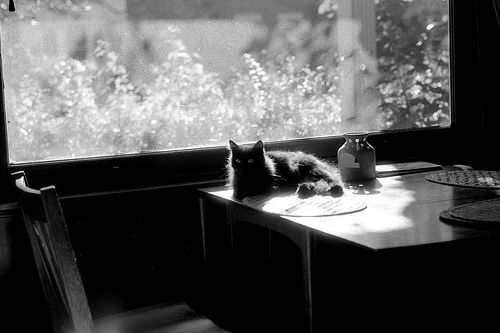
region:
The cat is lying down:
[222, 139, 344, 201]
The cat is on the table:
[199, 138, 496, 298]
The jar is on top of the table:
[333, 124, 378, 184]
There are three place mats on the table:
[239, 165, 497, 227]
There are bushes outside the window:
[3, 9, 454, 148]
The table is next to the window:
[3, 7, 495, 324]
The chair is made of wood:
[12, 168, 217, 330]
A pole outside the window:
[333, 1, 379, 131]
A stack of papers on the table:
[378, 157, 440, 182]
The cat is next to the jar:
[223, 129, 379, 200]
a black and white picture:
[22, 18, 426, 319]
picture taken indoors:
[34, 28, 475, 329]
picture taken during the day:
[18, 22, 461, 315]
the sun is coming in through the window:
[71, 33, 398, 250]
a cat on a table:
[206, 88, 383, 250]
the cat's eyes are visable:
[223, 148, 268, 169]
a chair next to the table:
[13, 157, 208, 332]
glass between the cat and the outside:
[91, 32, 409, 127]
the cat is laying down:
[216, 131, 351, 203]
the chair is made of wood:
[45, 226, 122, 291]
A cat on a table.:
[224, 138, 346, 203]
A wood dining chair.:
[8, 169, 225, 331]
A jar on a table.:
[336, 132, 377, 184]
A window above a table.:
[1, 1, 451, 168]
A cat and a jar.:
[226, 128, 378, 205]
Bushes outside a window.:
[3, 1, 454, 168]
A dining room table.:
[196, 158, 498, 330]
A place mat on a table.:
[241, 188, 368, 218]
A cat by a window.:
[224, 137, 346, 206]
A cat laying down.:
[226, 138, 346, 201]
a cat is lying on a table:
[194, 125, 437, 323]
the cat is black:
[217, 127, 347, 205]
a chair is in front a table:
[11, 156, 326, 323]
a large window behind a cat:
[0, 6, 481, 201]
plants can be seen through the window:
[6, 6, 461, 190]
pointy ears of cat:
[220, 135, 268, 154]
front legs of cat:
[228, 186, 276, 205]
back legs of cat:
[294, 172, 345, 199]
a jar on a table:
[333, 123, 390, 202]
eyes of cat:
[228, 150, 259, 167]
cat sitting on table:
[226, 139, 348, 198]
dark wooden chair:
[9, 172, 208, 329]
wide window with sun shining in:
[2, 8, 454, 157]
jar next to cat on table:
[335, 134, 373, 185]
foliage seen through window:
[25, 68, 325, 145]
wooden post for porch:
[327, 5, 394, 131]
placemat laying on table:
[429, 166, 496, 186]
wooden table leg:
[287, 230, 330, 329]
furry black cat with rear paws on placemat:
[215, 139, 359, 214]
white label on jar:
[340, 153, 360, 170]